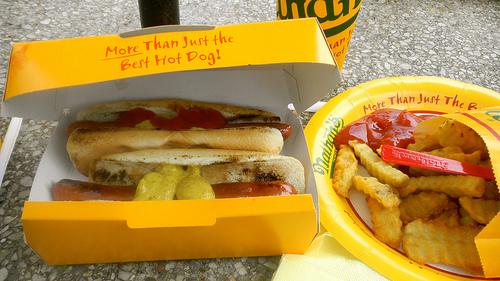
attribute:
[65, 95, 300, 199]
dogs — hot 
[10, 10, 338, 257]
carton — open 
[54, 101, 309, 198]
dogs — two hot 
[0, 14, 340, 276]
carton — yellow, top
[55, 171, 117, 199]
dog — cooked hot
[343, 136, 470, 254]
fries — frech 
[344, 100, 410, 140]
plate — paper 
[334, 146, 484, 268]
fries — crinkle cut french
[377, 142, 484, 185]
utensil — red plastic, handle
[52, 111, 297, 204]
dogs — two hot 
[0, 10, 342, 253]
container — paper , hot dog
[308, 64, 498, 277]
paper plate — yellow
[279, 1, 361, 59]
drink cup — paper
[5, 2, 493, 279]
tabletop — granite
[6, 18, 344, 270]
box — yellow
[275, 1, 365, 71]
drink cup — pictured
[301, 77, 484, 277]
plate — yellow